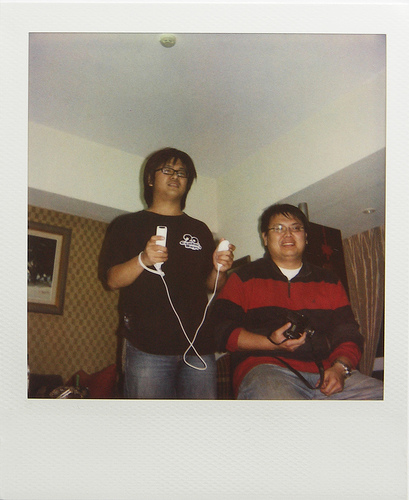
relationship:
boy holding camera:
[209, 200, 383, 402] [278, 309, 321, 352]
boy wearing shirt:
[97, 145, 237, 401] [96, 209, 215, 355]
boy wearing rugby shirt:
[209, 200, 383, 402] [212, 258, 366, 399]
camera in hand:
[266, 310, 327, 391] [268, 319, 306, 351]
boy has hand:
[209, 200, 383, 402] [268, 319, 306, 351]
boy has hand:
[209, 200, 383, 402] [319, 365, 345, 394]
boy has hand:
[97, 145, 237, 401] [143, 232, 167, 265]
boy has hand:
[97, 145, 237, 401] [209, 239, 235, 271]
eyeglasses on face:
[146, 167, 217, 188] [153, 160, 214, 209]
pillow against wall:
[65, 364, 119, 396] [27, 205, 118, 383]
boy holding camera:
[202, 204, 376, 397] [280, 316, 317, 345]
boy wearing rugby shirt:
[209, 200, 383, 402] [212, 262, 363, 369]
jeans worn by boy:
[121, 340, 385, 400] [94, 148, 218, 394]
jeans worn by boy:
[121, 340, 385, 400] [202, 204, 376, 397]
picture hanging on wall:
[26, 216, 75, 318] [32, 201, 182, 401]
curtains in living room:
[336, 243, 399, 330] [35, 42, 378, 392]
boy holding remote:
[97, 145, 237, 401] [143, 218, 177, 276]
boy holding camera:
[97, 145, 237, 401] [263, 319, 329, 388]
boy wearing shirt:
[209, 200, 383, 402] [207, 248, 365, 385]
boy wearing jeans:
[97, 145, 237, 401] [118, 341, 213, 395]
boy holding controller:
[97, 145, 237, 401] [138, 215, 232, 373]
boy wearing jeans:
[209, 200, 383, 402] [236, 367, 384, 400]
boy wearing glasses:
[209, 200, 383, 402] [262, 222, 305, 232]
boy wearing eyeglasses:
[97, 145, 237, 401] [153, 167, 190, 178]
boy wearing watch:
[209, 200, 383, 402] [331, 354, 356, 374]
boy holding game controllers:
[209, 200, 383, 402] [130, 225, 237, 375]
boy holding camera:
[209, 200, 383, 402] [271, 302, 321, 350]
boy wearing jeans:
[97, 145, 237, 401] [120, 347, 221, 398]